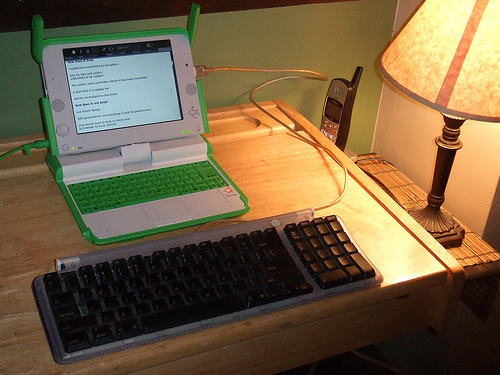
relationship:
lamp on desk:
[377, 0, 499, 247] [1, 99, 466, 374]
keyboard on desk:
[32, 207, 386, 367] [1, 99, 466, 374]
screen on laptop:
[62, 39, 184, 136] [29, 4, 253, 247]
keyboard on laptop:
[68, 161, 228, 215] [29, 4, 253, 247]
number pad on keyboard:
[284, 214, 377, 290] [32, 207, 386, 367]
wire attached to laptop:
[0, 137, 48, 160] [29, 4, 253, 247]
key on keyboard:
[61, 331, 92, 353] [32, 207, 386, 367]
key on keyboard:
[89, 323, 116, 346] [32, 207, 386, 367]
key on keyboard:
[115, 319, 142, 338] [32, 207, 386, 367]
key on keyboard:
[242, 286, 269, 308] [32, 207, 386, 367]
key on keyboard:
[55, 313, 99, 335] [32, 207, 386, 367]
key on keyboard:
[97, 309, 119, 325] [32, 207, 386, 367]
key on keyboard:
[115, 305, 135, 322] [32, 207, 386, 367]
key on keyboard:
[131, 301, 152, 317] [32, 207, 386, 367]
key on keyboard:
[152, 299, 168, 312] [32, 207, 386, 367]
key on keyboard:
[168, 293, 188, 310] [32, 207, 386, 367]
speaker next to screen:
[184, 81, 198, 96] [62, 39, 184, 136]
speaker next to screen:
[50, 96, 66, 113] [62, 39, 184, 136]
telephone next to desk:
[319, 65, 365, 152] [1, 99, 466, 374]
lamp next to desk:
[377, 0, 499, 247] [1, 99, 466, 374]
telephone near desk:
[319, 65, 365, 152] [1, 99, 466, 374]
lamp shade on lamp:
[377, 0, 499, 124] [377, 0, 499, 247]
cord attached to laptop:
[195, 63, 349, 215] [29, 4, 253, 247]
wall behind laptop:
[1, 0, 400, 157] [29, 4, 253, 247]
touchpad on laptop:
[141, 197, 192, 224] [29, 4, 253, 247]